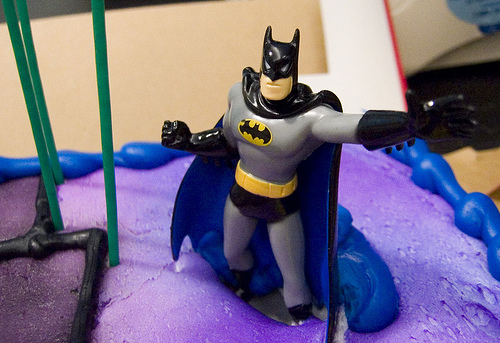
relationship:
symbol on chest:
[231, 115, 279, 153] [200, 95, 342, 179]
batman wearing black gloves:
[159, 26, 477, 326] [161, 112, 236, 154]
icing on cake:
[0, 176, 107, 341] [3, 196, 497, 343]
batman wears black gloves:
[159, 26, 477, 326] [356, 93, 478, 152]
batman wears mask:
[159, 26, 477, 326] [253, 67, 298, 98]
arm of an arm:
[311, 109, 416, 151] [301, 72, 484, 164]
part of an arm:
[376, 120, 427, 138] [361, 108, 432, 155]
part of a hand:
[355, 69, 435, 169] [323, 99, 435, 189]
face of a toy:
[257, 25, 301, 98] [160, 23, 479, 328]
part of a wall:
[123, 68, 191, 166] [0, 4, 407, 159]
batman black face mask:
[159, 26, 477, 326] [252, 22, 301, 95]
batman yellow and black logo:
[198, 67, 351, 293] [234, 111, 275, 149]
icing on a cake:
[0, 137, 500, 343] [3, 196, 497, 343]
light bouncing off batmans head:
[267, 49, 273, 58] [260, 25, 301, 99]